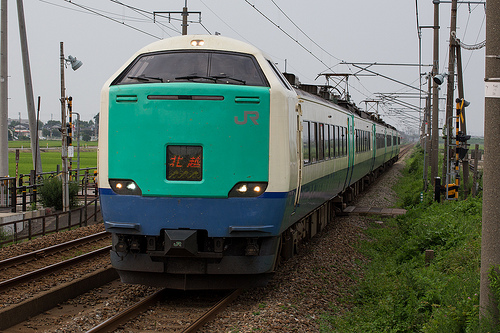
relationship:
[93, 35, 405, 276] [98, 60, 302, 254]
train has front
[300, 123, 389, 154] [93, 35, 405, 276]
windows are on side of train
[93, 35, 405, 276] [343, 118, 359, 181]
train has door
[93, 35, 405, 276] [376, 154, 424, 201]
train on track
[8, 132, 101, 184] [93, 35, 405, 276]
grass beside train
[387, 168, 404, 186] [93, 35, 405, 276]
rocks near train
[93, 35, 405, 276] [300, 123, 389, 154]
train has windows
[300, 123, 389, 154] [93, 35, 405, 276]
windows on side train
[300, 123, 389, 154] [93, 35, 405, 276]
windows on side of train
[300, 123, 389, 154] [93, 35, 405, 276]
windows on train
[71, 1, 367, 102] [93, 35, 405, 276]
lines are above train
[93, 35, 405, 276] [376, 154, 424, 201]
train on top of track